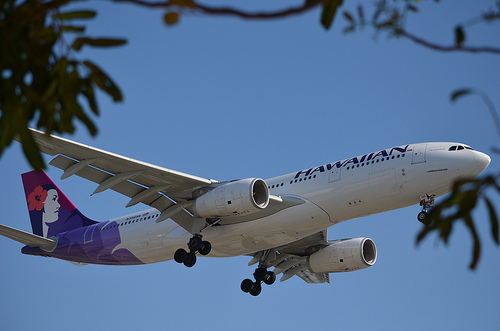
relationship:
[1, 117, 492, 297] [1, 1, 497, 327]
plane in sky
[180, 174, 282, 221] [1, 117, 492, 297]
right engine of plane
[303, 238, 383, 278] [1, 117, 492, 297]
left engine of plane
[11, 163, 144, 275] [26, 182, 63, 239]
graphic of woman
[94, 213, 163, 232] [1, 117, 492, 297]
rear windows of plane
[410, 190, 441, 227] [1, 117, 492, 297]
front wheels of plane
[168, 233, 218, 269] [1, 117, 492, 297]
rear right wheels of plane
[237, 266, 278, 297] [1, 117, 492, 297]
rear left wheels of plane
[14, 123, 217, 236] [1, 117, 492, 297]
right wing of plane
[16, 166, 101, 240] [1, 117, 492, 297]
tail of plane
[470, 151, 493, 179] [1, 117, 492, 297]
nose of plane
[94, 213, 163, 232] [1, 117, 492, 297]
rear windows on plane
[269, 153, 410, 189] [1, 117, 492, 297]
front windows on plane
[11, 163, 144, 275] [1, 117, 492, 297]
graphic on plane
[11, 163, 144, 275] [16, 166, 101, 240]
graphic on tail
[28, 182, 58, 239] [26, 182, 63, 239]
hair of woman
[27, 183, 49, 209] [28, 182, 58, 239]
flower in hair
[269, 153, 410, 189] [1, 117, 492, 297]
front windows of plane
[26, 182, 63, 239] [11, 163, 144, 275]
woman in graphic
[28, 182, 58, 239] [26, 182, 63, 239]
hair on woman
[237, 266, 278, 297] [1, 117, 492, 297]
rear left wheels on plane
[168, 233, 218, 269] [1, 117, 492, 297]
rear right wheels on plane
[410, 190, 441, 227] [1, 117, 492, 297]
front wheels on plane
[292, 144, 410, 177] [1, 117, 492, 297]
writing on side of plane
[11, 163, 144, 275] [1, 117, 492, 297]
graphic on rear of plane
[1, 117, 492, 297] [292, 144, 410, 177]
plane has writing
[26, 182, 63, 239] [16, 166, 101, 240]
woman on tail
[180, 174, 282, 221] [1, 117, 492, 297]
right engine on plane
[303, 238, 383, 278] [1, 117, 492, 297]
left engine on plane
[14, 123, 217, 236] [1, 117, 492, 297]
right wing on plane